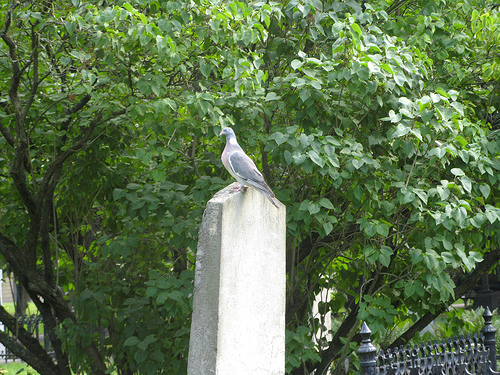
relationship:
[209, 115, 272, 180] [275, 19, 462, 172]
bird near trees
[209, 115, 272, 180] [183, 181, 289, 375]
bird on monument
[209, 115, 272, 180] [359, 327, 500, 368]
bird near fence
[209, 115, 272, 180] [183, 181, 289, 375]
bird near monument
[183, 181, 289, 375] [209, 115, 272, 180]
monument near bird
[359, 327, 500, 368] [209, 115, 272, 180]
fence near bird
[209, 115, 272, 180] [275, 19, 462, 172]
bird in trees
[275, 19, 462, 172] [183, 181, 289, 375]
trees near monument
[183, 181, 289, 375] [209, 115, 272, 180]
monument on bird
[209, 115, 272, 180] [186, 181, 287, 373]
bird sitting atop monument